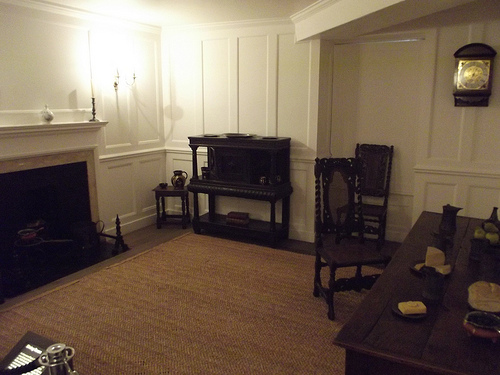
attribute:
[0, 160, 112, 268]
fire place — black  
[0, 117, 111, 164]
mantle — white 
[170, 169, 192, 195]
picture — dark metal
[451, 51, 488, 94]
clock — fancy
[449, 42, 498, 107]
clock — silver, brown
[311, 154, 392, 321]
chair — dark, wooden, dark brown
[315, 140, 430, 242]
chair — dark, wooden, high backed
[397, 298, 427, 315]
square — white 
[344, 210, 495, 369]
table — brown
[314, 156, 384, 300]
wooden chair — dark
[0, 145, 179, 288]
fireplace — white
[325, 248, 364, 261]
dark brown — oak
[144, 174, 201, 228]
table — small, brown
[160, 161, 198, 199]
jug — silver, small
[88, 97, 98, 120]
candle holder — silver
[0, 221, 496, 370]
carpet — brown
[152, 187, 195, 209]
table — wooden, dark, small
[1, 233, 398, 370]
rug — tan, large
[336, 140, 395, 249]
chair — wooden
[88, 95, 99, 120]
candlebar — metal